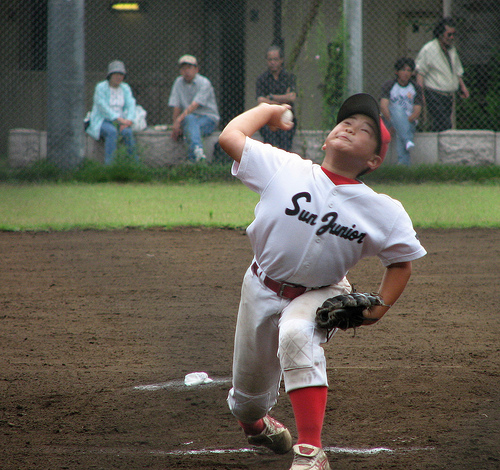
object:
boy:
[219, 92, 427, 470]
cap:
[336, 93, 390, 175]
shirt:
[231, 136, 427, 289]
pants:
[227, 259, 353, 424]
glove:
[314, 291, 391, 343]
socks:
[286, 386, 328, 450]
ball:
[277, 105, 293, 124]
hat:
[105, 59, 127, 81]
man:
[167, 53, 221, 162]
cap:
[177, 54, 198, 69]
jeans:
[100, 120, 139, 166]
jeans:
[182, 113, 218, 163]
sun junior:
[283, 189, 367, 245]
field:
[0, 224, 499, 470]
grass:
[0, 180, 499, 233]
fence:
[0, 0, 500, 182]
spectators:
[84, 59, 140, 164]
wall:
[1, 133, 499, 167]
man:
[255, 42, 298, 152]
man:
[379, 56, 423, 165]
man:
[413, 18, 470, 131]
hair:
[432, 19, 456, 39]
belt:
[250, 261, 331, 300]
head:
[321, 93, 391, 171]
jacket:
[85, 79, 136, 142]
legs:
[181, 114, 206, 163]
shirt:
[255, 67, 299, 118]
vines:
[330, 20, 345, 62]